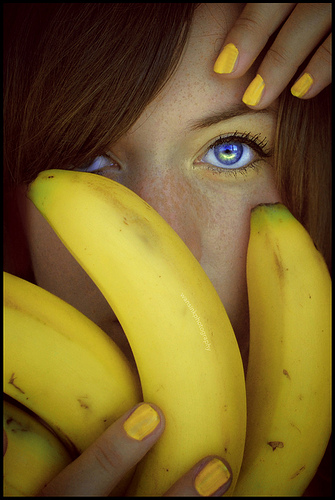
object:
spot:
[267, 438, 289, 455]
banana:
[237, 206, 335, 499]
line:
[269, 246, 294, 292]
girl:
[0, 13, 333, 493]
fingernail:
[213, 43, 239, 74]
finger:
[213, 0, 295, 81]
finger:
[27, 397, 167, 496]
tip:
[252, 199, 288, 216]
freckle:
[183, 190, 206, 207]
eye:
[200, 133, 272, 173]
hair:
[5, 6, 334, 259]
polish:
[245, 85, 261, 97]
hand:
[0, 404, 236, 500]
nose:
[135, 170, 208, 260]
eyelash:
[212, 133, 271, 161]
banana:
[26, 167, 247, 499]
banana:
[2, 272, 149, 478]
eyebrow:
[189, 97, 282, 125]